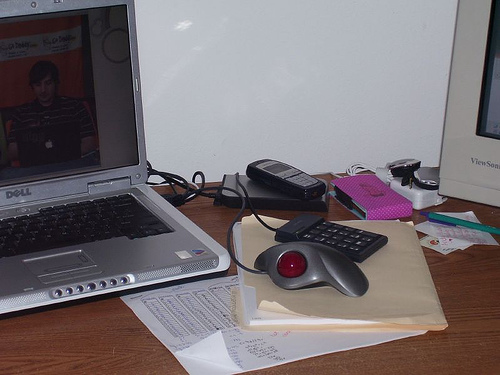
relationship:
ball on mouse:
[276, 250, 311, 283] [260, 234, 368, 303]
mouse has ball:
[260, 234, 368, 303] [276, 250, 311, 283]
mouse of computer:
[260, 234, 368, 303] [2, 5, 235, 315]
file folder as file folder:
[233, 209, 449, 372] [230, 212, 449, 334]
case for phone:
[335, 177, 396, 215] [248, 155, 320, 204]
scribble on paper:
[237, 332, 284, 361] [166, 316, 259, 374]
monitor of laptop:
[3, 9, 141, 178] [2, 5, 235, 315]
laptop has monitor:
[2, 5, 235, 315] [3, 9, 141, 178]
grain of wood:
[48, 329, 102, 366] [7, 327, 145, 372]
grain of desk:
[48, 329, 102, 366] [7, 188, 499, 372]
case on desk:
[335, 177, 396, 215] [7, 188, 499, 372]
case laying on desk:
[335, 177, 396, 215] [7, 188, 499, 372]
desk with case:
[7, 188, 499, 372] [335, 177, 396, 215]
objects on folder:
[260, 211, 379, 289] [233, 209, 449, 372]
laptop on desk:
[2, 5, 235, 315] [7, 188, 499, 372]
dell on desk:
[5, 174, 75, 210] [7, 188, 499, 372]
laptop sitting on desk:
[2, 5, 235, 315] [7, 188, 499, 372]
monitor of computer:
[3, 9, 141, 178] [2, 5, 235, 315]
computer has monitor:
[2, 5, 235, 315] [3, 9, 141, 178]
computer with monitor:
[2, 5, 235, 315] [3, 9, 141, 178]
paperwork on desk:
[146, 198, 453, 371] [7, 188, 499, 372]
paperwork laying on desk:
[146, 198, 453, 371] [7, 188, 499, 372]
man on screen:
[13, 67, 96, 153] [3, 9, 141, 178]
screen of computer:
[3, 9, 141, 178] [2, 5, 235, 315]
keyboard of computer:
[4, 196, 156, 245] [2, 5, 235, 315]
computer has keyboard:
[2, 5, 235, 315] [4, 196, 156, 245]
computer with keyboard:
[2, 5, 235, 315] [4, 196, 156, 245]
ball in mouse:
[276, 250, 311, 283] [260, 234, 368, 303]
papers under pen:
[424, 210, 485, 266] [420, 204, 499, 240]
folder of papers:
[233, 209, 449, 372] [234, 221, 269, 327]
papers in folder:
[234, 221, 269, 327] [233, 209, 449, 372]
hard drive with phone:
[217, 171, 302, 211] [248, 155, 320, 204]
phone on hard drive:
[248, 155, 320, 204] [217, 171, 302, 211]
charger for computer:
[388, 165, 439, 210] [2, 5, 235, 315]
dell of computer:
[2, 183, 40, 202] [2, 5, 235, 315]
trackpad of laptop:
[22, 253, 105, 277] [2, 5, 235, 315]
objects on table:
[260, 211, 379, 289] [7, 188, 499, 372]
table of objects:
[7, 188, 499, 372] [260, 211, 379, 289]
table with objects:
[7, 188, 499, 372] [260, 211, 379, 289]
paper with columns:
[166, 316, 259, 374] [148, 291, 212, 338]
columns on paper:
[148, 291, 212, 338] [166, 316, 259, 374]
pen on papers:
[420, 204, 499, 240] [424, 210, 485, 266]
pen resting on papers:
[420, 204, 499, 240] [424, 210, 485, 266]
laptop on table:
[2, 5, 235, 315] [7, 188, 499, 372]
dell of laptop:
[2, 183, 40, 202] [2, 5, 235, 315]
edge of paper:
[170, 333, 252, 373] [166, 316, 259, 374]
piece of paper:
[141, 297, 233, 357] [166, 316, 259, 374]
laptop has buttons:
[2, 5, 235, 315] [51, 277, 134, 295]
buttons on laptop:
[51, 277, 134, 295] [2, 5, 235, 315]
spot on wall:
[177, 14, 192, 42] [152, 3, 410, 145]